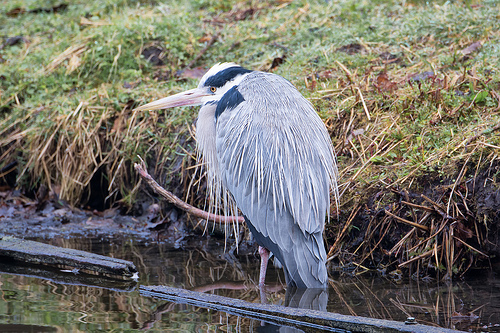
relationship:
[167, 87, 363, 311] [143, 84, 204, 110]
bird has beak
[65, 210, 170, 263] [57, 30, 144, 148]
water near grass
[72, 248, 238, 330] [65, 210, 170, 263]
stick in water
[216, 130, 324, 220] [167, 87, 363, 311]
wing of bird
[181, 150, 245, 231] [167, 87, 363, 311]
feathers on bird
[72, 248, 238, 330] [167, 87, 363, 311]
stick near bird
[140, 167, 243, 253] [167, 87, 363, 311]
leg of bird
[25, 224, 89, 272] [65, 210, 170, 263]
wood in water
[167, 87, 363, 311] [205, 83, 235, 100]
bird has eye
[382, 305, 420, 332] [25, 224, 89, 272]
bolt on wood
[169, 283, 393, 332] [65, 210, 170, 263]
board in water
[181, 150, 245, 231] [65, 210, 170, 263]
feathers in water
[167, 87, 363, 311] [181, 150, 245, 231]
bird has feathers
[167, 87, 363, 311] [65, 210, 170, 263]
bird by water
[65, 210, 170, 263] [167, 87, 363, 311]
water by bird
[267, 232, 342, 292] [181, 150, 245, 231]
tail with feathers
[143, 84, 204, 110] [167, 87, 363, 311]
beak of bird